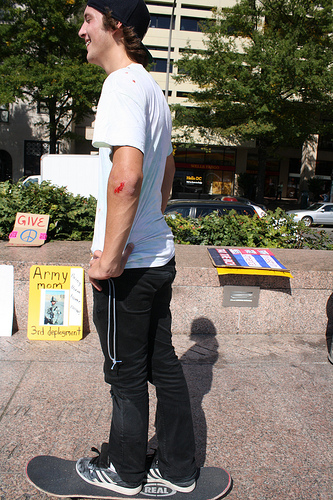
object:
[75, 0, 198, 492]
man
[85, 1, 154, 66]
hat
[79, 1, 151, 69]
head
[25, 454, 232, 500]
skateboard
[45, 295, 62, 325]
soldier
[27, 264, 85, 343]
sign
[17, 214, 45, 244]
give peace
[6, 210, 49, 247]
sign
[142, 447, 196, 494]
shoe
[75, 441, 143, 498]
shoe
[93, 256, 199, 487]
pants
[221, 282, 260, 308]
vent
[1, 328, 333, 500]
sidewalk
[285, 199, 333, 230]
car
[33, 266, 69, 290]
army mom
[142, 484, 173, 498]
logo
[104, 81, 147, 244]
arm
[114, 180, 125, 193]
blood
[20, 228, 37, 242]
peace sign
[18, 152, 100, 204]
truck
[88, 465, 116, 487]
stripes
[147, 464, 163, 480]
stripes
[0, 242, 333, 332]
ledge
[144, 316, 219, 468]
shadow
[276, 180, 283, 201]
person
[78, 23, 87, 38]
nose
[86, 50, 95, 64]
chin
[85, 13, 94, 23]
eye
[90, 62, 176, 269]
shirt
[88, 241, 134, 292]
hand